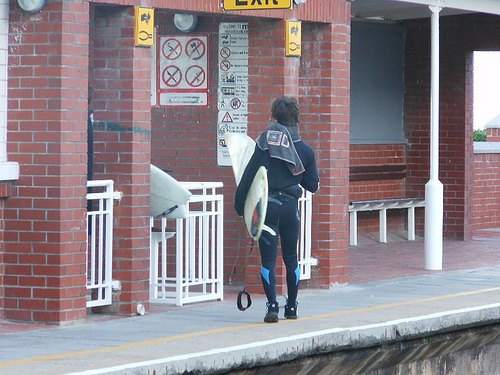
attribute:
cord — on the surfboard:
[227, 214, 255, 313]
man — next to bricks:
[228, 87, 332, 319]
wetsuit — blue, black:
[233, 130, 320, 329]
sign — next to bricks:
[215, 20, 252, 166]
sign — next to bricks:
[163, 65, 182, 87]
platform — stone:
[314, 282, 436, 354]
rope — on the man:
[229, 217, 255, 310]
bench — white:
[352, 148, 409, 262]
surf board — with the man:
[198, 116, 275, 250]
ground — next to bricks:
[421, 112, 468, 189]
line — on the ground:
[83, 305, 483, 369]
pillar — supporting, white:
[415, 4, 498, 246]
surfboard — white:
[218, 121, 286, 253]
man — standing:
[232, 95, 321, 324]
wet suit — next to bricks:
[242, 89, 338, 356]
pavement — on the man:
[0, 260, 500, 374]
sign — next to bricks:
[152, 30, 227, 114]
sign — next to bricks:
[182, 62, 206, 88]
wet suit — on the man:
[234, 126, 319, 303]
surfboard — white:
[221, 125, 271, 243]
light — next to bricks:
[168, 12, 200, 32]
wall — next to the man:
[29, 25, 328, 304]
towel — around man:
[284, 135, 295, 160]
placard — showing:
[155, 30, 212, 105]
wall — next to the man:
[325, 23, 346, 283]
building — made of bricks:
[2, 0, 499, 330]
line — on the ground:
[9, 257, 499, 366]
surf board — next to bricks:
[208, 114, 279, 243]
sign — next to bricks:
[160, 36, 212, 107]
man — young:
[194, 77, 323, 317]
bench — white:
[361, 192, 394, 239]